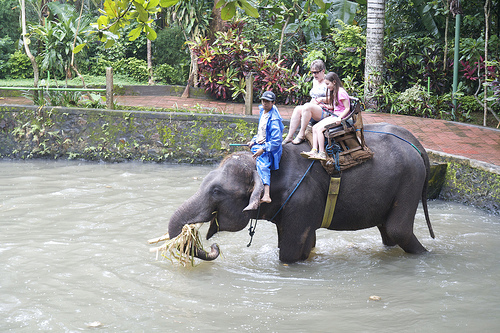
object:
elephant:
[168, 121, 435, 263]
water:
[4, 159, 500, 329]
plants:
[8, 118, 63, 149]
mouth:
[187, 205, 233, 240]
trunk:
[147, 210, 220, 268]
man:
[242, 90, 284, 212]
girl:
[299, 72, 350, 162]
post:
[106, 67, 114, 110]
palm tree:
[362, 0, 387, 112]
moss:
[95, 115, 144, 138]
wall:
[0, 102, 500, 219]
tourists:
[280, 59, 334, 145]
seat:
[304, 96, 375, 175]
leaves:
[148, 224, 208, 267]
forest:
[0, 0, 500, 115]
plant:
[188, 37, 307, 101]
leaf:
[461, 38, 485, 64]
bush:
[388, 24, 497, 116]